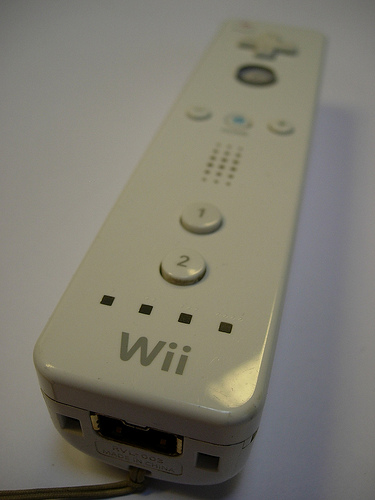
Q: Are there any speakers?
A: Yes, there is a speaker.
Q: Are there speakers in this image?
A: Yes, there is a speaker.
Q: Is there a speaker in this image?
A: Yes, there is a speaker.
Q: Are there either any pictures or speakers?
A: Yes, there is a speaker.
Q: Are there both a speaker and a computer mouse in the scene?
A: No, there is a speaker but no computer mice.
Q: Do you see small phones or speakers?
A: Yes, there is a small speaker.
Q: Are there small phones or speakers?
A: Yes, there is a small speaker.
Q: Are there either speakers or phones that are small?
A: Yes, the speaker is small.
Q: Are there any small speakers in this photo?
A: Yes, there is a small speaker.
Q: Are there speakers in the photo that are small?
A: Yes, there is a speaker that is small.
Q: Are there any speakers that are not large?
A: Yes, there is a small speaker.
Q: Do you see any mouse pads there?
A: No, there are no mouse pads.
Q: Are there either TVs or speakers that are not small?
A: No, there is a speaker but it is small.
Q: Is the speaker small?
A: Yes, the speaker is small.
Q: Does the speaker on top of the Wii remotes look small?
A: Yes, the speaker is small.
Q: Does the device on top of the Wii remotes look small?
A: Yes, the speaker is small.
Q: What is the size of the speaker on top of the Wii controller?
A: The speaker is small.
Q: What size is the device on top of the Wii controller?
A: The speaker is small.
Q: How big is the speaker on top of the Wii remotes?
A: The speaker is small.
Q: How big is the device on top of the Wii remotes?
A: The speaker is small.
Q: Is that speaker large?
A: No, the speaker is small.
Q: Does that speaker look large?
A: No, the speaker is small.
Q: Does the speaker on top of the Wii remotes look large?
A: No, the speaker is small.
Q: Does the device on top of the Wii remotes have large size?
A: No, the speaker is small.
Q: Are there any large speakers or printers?
A: No, there is a speaker but it is small.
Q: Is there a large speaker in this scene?
A: No, there is a speaker but it is small.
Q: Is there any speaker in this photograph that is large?
A: No, there is a speaker but it is small.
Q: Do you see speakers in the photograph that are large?
A: No, there is a speaker but it is small.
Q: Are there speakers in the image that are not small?
A: No, there is a speaker but it is small.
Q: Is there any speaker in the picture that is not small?
A: No, there is a speaker but it is small.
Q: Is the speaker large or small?
A: The speaker is small.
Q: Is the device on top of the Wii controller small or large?
A: The speaker is small.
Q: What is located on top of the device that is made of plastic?
A: The speaker is on top of the Wii controller.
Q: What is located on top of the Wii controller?
A: The speaker is on top of the Wii controller.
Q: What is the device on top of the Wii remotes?
A: The device is a speaker.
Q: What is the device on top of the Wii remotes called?
A: The device is a speaker.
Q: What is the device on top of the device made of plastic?
A: The device is a speaker.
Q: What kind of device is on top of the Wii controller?
A: The device is a speaker.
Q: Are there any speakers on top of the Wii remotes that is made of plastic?
A: Yes, there is a speaker on top of the Wii remotes.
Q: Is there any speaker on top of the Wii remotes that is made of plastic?
A: Yes, there is a speaker on top of the Wii remotes.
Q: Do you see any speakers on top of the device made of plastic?
A: Yes, there is a speaker on top of the Wii remotes.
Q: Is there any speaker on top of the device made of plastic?
A: Yes, there is a speaker on top of the Wii remotes.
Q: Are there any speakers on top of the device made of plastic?
A: Yes, there is a speaker on top of the Wii remotes.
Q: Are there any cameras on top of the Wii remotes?
A: No, there is a speaker on top of the Wii remotes.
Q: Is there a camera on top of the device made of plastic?
A: No, there is a speaker on top of the Wii remotes.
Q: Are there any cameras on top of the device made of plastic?
A: No, there is a speaker on top of the Wii remotes.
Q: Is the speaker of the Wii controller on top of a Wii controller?
A: Yes, the speaker is on top of a Wii controller.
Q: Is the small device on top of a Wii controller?
A: Yes, the speaker is on top of a Wii controller.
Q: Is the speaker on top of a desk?
A: No, the speaker is on top of a Wii controller.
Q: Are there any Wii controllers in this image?
A: Yes, there is a Wii controller.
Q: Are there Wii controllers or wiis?
A: Yes, there is a Wii controller.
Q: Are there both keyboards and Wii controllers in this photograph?
A: No, there is a Wii controller but no keyboards.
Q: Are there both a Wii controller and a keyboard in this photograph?
A: No, there is a Wii controller but no keyboards.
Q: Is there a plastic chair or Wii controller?
A: Yes, there is a plastic Wii controller.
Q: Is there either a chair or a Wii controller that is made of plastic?
A: Yes, the Wii controller is made of plastic.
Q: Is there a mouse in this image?
A: No, there are no computer mice.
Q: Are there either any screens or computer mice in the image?
A: No, there are no computer mice or screens.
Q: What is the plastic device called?
A: The device is a Wii controller.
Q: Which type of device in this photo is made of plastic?
A: The device is a Wii controller.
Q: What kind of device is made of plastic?
A: The device is a Wii controller.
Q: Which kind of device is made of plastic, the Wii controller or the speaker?
A: The Wii controller is made of plastic.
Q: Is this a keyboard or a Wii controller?
A: This is a Wii controller.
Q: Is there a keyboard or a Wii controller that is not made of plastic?
A: No, there is a Wii controller but it is made of plastic.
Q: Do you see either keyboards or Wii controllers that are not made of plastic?
A: No, there is a Wii controller but it is made of plastic.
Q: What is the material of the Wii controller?
A: The Wii controller is made of plastic.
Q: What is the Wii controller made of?
A: The Wii controller is made of plastic.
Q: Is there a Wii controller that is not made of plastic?
A: No, there is a Wii controller but it is made of plastic.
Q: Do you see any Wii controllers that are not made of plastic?
A: No, there is a Wii controller but it is made of plastic.